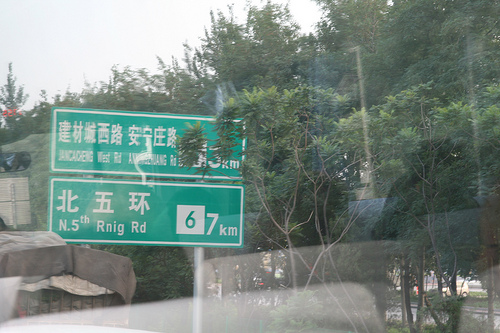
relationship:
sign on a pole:
[68, 105, 295, 214] [192, 245, 207, 331]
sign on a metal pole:
[46, 177, 246, 252] [192, 246, 207, 331]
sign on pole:
[51, 105, 254, 184] [191, 239, 211, 332]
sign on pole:
[46, 177, 246, 252] [191, 239, 211, 332]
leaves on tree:
[345, 27, 495, 205] [357, 11, 464, 326]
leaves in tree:
[376, 5, 420, 41] [374, 5, 454, 62]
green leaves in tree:
[377, 34, 399, 50] [293, 0, 438, 99]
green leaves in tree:
[411, 20, 432, 39] [293, 0, 438, 99]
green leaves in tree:
[319, 65, 341, 79] [293, 0, 438, 99]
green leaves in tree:
[365, 78, 381, 90] [293, 0, 438, 99]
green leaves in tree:
[339, 92, 354, 104] [293, 0, 438, 99]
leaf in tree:
[270, 169, 276, 178] [168, 80, 418, 327]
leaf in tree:
[311, 132, 318, 142] [168, 80, 418, 327]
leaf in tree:
[323, 131, 328, 141] [168, 80, 418, 327]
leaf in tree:
[299, 153, 309, 159] [168, 80, 418, 327]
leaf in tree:
[259, 122, 268, 131] [168, 80, 418, 327]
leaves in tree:
[0, 0, 474, 281] [271, 17, 499, 237]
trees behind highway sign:
[158, 8, 320, 298] [47, 105, 251, 248]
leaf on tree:
[446, 100, 457, 113] [368, 80, 495, 332]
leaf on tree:
[381, 90, 396, 102] [368, 80, 495, 332]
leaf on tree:
[422, 78, 433, 91] [368, 80, 495, 332]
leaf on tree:
[378, 106, 388, 117] [368, 80, 495, 332]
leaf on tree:
[431, 112, 441, 120] [368, 80, 495, 332]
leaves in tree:
[284, 8, 498, 128] [250, 113, 495, 330]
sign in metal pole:
[46, 177, 246, 252] [192, 246, 207, 331]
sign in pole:
[46, 177, 246, 252] [192, 245, 202, 331]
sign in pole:
[51, 105, 254, 184] [192, 245, 202, 331]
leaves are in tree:
[326, 93, 374, 141] [296, 77, 475, 250]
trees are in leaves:
[171, 79, 385, 333] [243, 86, 281, 122]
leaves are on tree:
[416, 64, 454, 93] [378, 75, 492, 320]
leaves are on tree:
[391, 88, 475, 167] [369, 55, 446, 298]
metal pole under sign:
[192, 246, 207, 331] [48, 98, 258, 254]